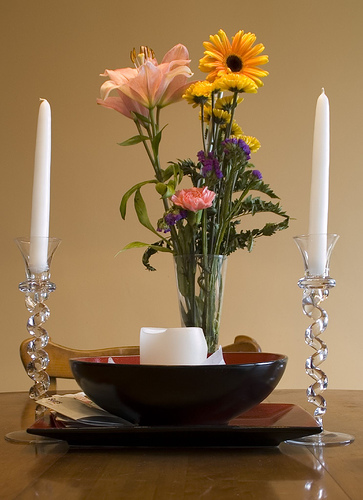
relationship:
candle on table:
[307, 88, 328, 275] [1, 390, 361, 499]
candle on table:
[29, 97, 51, 274] [1, 390, 361, 499]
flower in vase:
[222, 134, 251, 162] [171, 256, 226, 350]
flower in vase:
[252, 168, 262, 182] [171, 256, 226, 350]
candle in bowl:
[138, 323, 208, 364] [68, 352, 288, 425]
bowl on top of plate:
[68, 352, 288, 425] [25, 401, 320, 450]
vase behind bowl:
[171, 256, 226, 350] [68, 352, 288, 425]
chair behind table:
[19, 334, 261, 392] [1, 390, 361, 499]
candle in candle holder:
[307, 88, 328, 275] [282, 231, 354, 448]